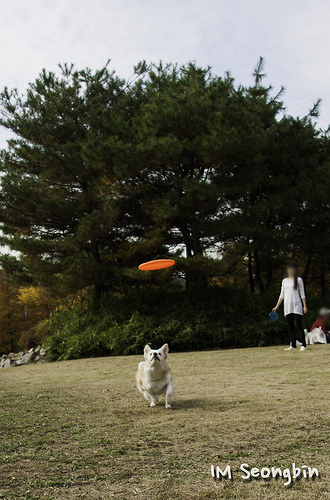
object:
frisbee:
[136, 258, 177, 273]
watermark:
[210, 460, 320, 484]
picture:
[0, 0, 330, 500]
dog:
[135, 342, 173, 410]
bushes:
[40, 284, 287, 362]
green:
[151, 306, 177, 334]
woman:
[270, 259, 310, 350]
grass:
[0, 389, 329, 497]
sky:
[0, 0, 330, 279]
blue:
[118, 7, 203, 51]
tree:
[0, 55, 330, 309]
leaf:
[26, 292, 31, 298]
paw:
[165, 403, 171, 410]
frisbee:
[268, 312, 280, 323]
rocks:
[15, 353, 30, 366]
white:
[278, 283, 304, 314]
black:
[285, 318, 304, 343]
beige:
[146, 372, 166, 391]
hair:
[283, 258, 298, 291]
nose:
[153, 352, 157, 356]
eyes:
[149, 353, 153, 356]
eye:
[158, 352, 161, 356]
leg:
[139, 387, 157, 402]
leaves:
[258, 73, 263, 78]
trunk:
[254, 249, 266, 293]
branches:
[299, 99, 323, 123]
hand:
[302, 307, 308, 314]